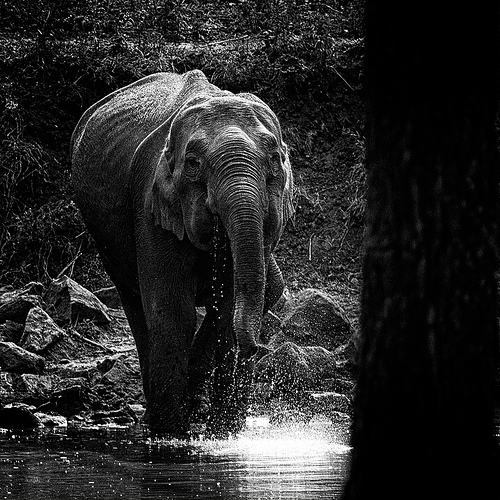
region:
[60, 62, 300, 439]
large grey elephant standing in the water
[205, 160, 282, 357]
trunk of a large grey elephant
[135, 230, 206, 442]
leg of a large grey elephant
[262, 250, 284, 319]
leg of a large grey elephant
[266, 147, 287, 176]
eye of a large grey elephant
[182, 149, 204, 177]
eye of a large grey elephant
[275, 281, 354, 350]
large rock near the water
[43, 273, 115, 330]
large rock near the water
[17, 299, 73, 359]
large rock near the water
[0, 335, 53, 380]
large rock near the water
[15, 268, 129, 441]
big rock on the ground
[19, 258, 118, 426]
big rock on the ground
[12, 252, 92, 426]
big rock on the ground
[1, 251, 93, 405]
big rock on the ground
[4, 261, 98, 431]
big rock on the ground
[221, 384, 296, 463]
the splashes of water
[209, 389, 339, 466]
the splashes of water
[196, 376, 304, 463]
the splashes of water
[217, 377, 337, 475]
the splashes of water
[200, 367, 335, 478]
the splashes of water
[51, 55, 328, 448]
elephant walking in the water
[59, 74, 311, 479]
elephant walking in the water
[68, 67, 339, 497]
elephant walking in the water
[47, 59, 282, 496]
elephant walking in the water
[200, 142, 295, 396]
lines on elephant's nose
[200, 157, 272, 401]
lines on elephant's nose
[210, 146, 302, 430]
lines on elephant's nose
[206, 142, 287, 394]
lines on elephant's nose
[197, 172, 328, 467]
lines on elephant's nose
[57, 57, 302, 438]
An elephant in the photo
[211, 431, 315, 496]
A water in the photo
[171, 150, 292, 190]
Eyes of an elephant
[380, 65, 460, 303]
A tree trunk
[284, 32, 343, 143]
Trees at the back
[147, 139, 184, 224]
Ear of an elephant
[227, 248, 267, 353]
A trunk of an elephant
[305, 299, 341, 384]
Rocks in the photo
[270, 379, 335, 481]
River in the forest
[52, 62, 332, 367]
An elephant on the water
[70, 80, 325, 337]
A big grey elepahant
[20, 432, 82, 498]
A clean water stream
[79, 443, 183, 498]
A clean water stream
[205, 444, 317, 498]
A clean water stream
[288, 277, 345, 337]
A big stone by the stream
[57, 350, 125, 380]
A big stone by the stream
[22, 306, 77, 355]
A big stone by the stream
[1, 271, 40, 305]
A big stone by the stream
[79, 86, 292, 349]
big elephant in the water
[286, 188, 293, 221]
left ear of the elephant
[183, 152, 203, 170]
right eye of the elephant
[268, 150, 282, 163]
left eye of the elephant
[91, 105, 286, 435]
big elephant walking in the water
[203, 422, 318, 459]
white splash in the water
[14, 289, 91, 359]
rock pile in the left side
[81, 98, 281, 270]
big and old elephant walk in the water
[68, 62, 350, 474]
the elephant is splashing water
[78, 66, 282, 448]
the elephant's feet are in the water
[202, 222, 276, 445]
water is dripping from the elephant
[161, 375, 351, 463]
water is splashing about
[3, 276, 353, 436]
rocks are at the water's edge